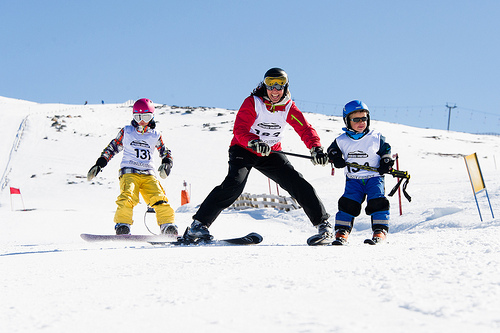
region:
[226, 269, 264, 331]
part of a ground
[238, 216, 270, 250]
part of a board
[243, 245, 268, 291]
part of a snow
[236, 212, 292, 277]
part of a board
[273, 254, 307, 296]
part of a ground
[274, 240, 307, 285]
part fo a snow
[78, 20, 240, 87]
the sky is blue in colour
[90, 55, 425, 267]
three people are skiing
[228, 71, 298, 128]
the woman is laughing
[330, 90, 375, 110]
the helmet is blue in colour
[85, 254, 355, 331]
the snow is white in colour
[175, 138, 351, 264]
her legs are apart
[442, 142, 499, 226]
the sign is yellow in colour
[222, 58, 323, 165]
the jacket is red in colour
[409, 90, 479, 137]
a black electric post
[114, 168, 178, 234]
yellow pants are worn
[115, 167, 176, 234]
The yellow pants the skier is wearing.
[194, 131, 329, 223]
The black pants the skier is wearing.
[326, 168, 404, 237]
The blue and black pants the skier is wearing.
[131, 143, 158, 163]
The number 131 on the skier's chest.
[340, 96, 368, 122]
The blue helmet the kid is wearing.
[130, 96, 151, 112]
The pink helmet the kid is wearing.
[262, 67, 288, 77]
The black helmet the adult is wearing.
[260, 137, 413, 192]
The pole the kid on the right is holding on to.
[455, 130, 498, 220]
The yellow sign to the right of the kid.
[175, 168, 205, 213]
The orange cone behind the kid in yellow pants.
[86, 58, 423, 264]
a person with kids and snowboard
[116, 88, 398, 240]
three people wearing snowsuit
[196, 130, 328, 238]
person wearing black color pant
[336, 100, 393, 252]
a child holding ski pole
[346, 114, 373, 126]
a child wearing eyeglasses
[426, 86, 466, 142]
electric post in the snow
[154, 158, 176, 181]
a child wearing gloves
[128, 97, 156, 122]
a child wearing helmet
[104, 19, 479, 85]
blue color sky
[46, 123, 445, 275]
mountain covered with snow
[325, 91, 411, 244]
little boy wearing a white and blue outfit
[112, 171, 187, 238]
child wearing yellow pants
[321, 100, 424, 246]
child wearing protective gear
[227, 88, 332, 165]
woman wearing red jacket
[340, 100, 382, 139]
child wearing a blue helmet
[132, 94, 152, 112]
child wearing a red helmet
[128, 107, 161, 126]
child wearing white snow goggles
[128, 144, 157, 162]
numeration on child's chest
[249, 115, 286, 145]
numeration on woman's chest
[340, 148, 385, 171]
numeration on child's chest